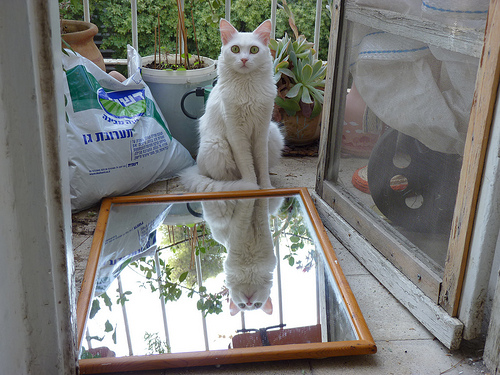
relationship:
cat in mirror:
[192, 14, 297, 189] [89, 198, 356, 360]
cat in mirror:
[175, 17, 287, 191] [77, 190, 389, 371]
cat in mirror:
[175, 17, 287, 191] [100, 188, 366, 361]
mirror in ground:
[77, 190, 389, 371] [378, 310, 421, 373]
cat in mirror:
[192, 14, 297, 189] [93, 203, 345, 353]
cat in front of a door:
[175, 17, 287, 191] [313, 5, 488, 332]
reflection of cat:
[199, 202, 283, 313] [175, 17, 287, 191]